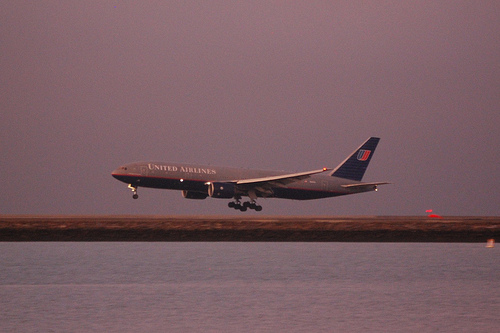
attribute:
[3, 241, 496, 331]
water — blue, calm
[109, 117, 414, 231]
airplane — gray, blue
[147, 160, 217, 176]
font — white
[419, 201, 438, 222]
windsock — orange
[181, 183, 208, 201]
engine — starboard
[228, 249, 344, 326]
water — calm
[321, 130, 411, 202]
wings — tail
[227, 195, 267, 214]
landing gear — rear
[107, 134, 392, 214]
plane — departing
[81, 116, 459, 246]
blue symbol — red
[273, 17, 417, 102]
sky — overcast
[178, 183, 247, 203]
engines — jet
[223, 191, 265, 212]
gear — landing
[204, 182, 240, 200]
engine — jet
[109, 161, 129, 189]
head — streamlined